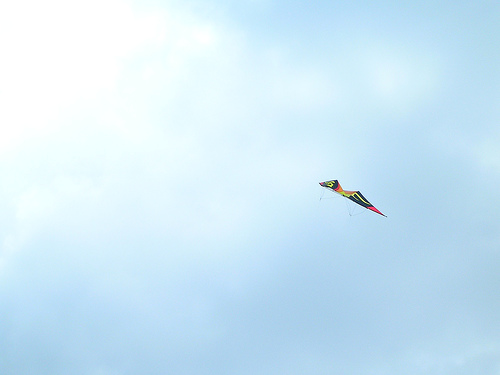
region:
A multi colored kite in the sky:
[316, 176, 390, 222]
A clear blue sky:
[1, 0, 498, 374]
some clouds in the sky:
[6, 5, 429, 282]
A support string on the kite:
[351, 207, 368, 217]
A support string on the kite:
[349, 203, 359, 218]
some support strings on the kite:
[319, 186, 326, 201]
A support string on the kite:
[320, 194, 341, 202]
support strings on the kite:
[317, 185, 368, 216]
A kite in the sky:
[314, 172, 389, 223]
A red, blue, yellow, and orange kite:
[314, 174, 390, 223]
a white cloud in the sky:
[2, 0, 207, 207]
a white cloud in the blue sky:
[5, 0, 216, 218]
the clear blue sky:
[0, 248, 237, 373]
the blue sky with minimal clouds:
[2, 221, 210, 374]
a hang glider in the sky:
[314, 174, 391, 230]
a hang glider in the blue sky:
[317, 179, 392, 219]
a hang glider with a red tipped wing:
[367, 206, 389, 217]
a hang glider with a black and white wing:
[350, 190, 371, 209]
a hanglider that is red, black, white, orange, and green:
[320, 177, 387, 219]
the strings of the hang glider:
[343, 201, 363, 214]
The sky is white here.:
[6, 20, 111, 118]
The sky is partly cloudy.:
[6, 25, 274, 231]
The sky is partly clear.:
[43, 70, 268, 327]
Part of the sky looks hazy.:
[26, 113, 286, 345]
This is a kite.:
[256, 128, 428, 274]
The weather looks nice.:
[73, 98, 269, 323]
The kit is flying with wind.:
[278, 151, 427, 262]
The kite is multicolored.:
[305, 173, 433, 261]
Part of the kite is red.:
[327, 180, 342, 193]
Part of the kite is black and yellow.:
[346, 190, 371, 209]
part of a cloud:
[207, 81, 251, 134]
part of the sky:
[308, 295, 349, 347]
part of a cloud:
[109, 190, 141, 212]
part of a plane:
[361, 188, 381, 214]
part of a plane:
[339, 158, 378, 240]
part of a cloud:
[128, 216, 206, 313]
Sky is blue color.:
[86, 218, 226, 318]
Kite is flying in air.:
[305, 165, 392, 252]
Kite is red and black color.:
[311, 166, 420, 246]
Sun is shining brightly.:
[23, 24, 104, 113]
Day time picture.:
[38, 52, 452, 341]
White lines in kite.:
[313, 168, 412, 240]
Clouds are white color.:
[196, 55, 311, 147]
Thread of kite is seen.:
[301, 186, 366, 230]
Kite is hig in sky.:
[302, 164, 393, 238]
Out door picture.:
[47, 55, 427, 324]